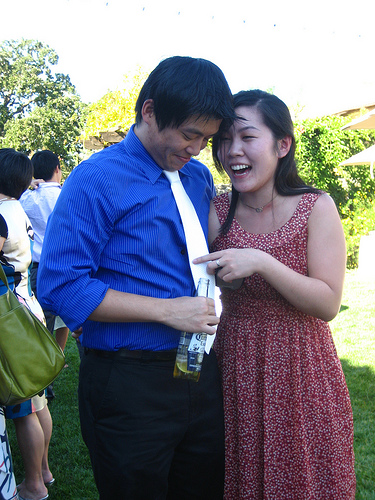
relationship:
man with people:
[99, 95, 218, 277] [192, 88, 345, 499]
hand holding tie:
[216, 249, 258, 284] [183, 208, 204, 261]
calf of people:
[29, 427, 53, 461] [192, 88, 345, 499]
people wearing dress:
[192, 88, 345, 499] [237, 326, 289, 380]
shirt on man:
[103, 197, 167, 285] [99, 95, 218, 277]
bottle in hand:
[184, 319, 209, 356] [216, 249, 258, 284]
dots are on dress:
[274, 245, 299, 256] [237, 326, 289, 380]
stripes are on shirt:
[127, 193, 158, 241] [103, 197, 167, 285]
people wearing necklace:
[192, 88, 345, 499] [242, 197, 271, 226]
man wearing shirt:
[99, 95, 218, 277] [103, 197, 167, 285]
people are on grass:
[25, 252, 300, 348] [344, 324, 372, 347]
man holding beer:
[99, 95, 218, 277] [175, 340, 214, 377]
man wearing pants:
[99, 95, 218, 277] [43, 366, 198, 479]